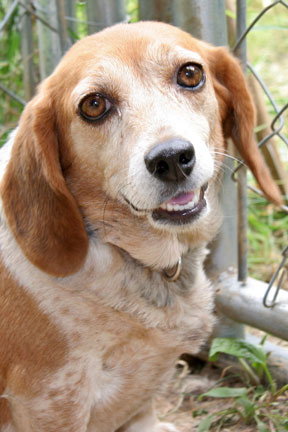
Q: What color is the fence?
A: Silver.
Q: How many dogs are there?
A: One.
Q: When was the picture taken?
A: Daytime.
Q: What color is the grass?
A: Green.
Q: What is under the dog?
A: Grass.